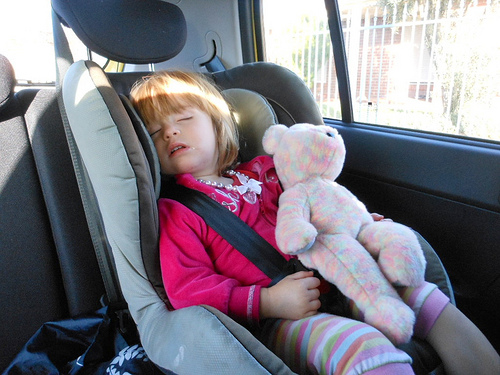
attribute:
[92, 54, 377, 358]
girl — sleeping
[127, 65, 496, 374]
kid — asleep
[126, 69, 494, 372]
child — sleeping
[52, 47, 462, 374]
car seat — grey, black, blue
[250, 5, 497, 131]
window — passenger, side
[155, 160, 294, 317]
pink jacket — hot pink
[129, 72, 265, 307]
girl — little, sleeping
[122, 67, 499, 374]
toddler — asleep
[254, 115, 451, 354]
teddybear — teddy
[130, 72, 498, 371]
girl — little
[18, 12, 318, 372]
seat — back